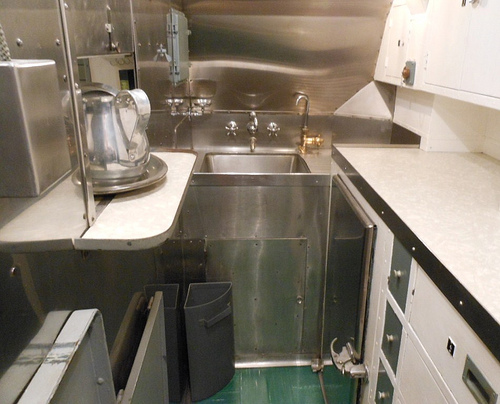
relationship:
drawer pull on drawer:
[394, 269, 402, 278] [383, 235, 423, 311]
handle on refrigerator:
[309, 314, 381, 402] [310, 174, 378, 402]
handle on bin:
[201, 303, 234, 329] [185, 282, 235, 401]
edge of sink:
[203, 167, 305, 177] [192, 112, 314, 177]